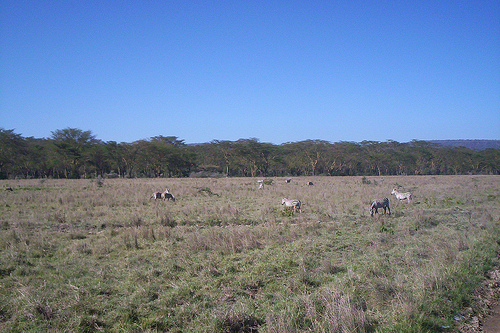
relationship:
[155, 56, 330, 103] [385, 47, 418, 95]
sky has clouds